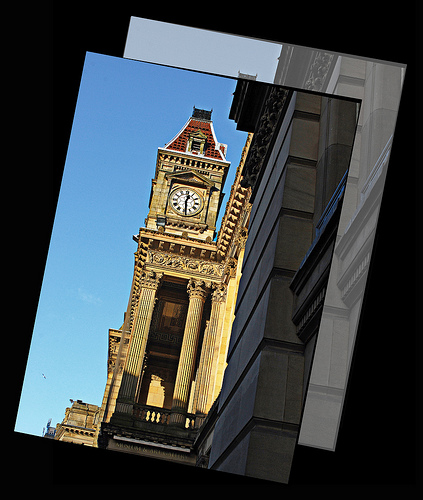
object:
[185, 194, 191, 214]
hand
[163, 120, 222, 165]
roof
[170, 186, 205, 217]
clock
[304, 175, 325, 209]
ground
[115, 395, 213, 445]
railing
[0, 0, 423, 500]
building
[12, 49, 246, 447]
sky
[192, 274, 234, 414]
surface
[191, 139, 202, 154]
window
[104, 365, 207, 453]
shadow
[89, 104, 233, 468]
clock tower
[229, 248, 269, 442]
wall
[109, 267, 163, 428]
column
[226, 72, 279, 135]
eaves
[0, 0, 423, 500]
photo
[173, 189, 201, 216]
clock face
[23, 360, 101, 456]
distance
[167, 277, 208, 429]
column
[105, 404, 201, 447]
porch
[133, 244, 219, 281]
sidework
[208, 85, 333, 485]
stone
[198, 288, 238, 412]
light